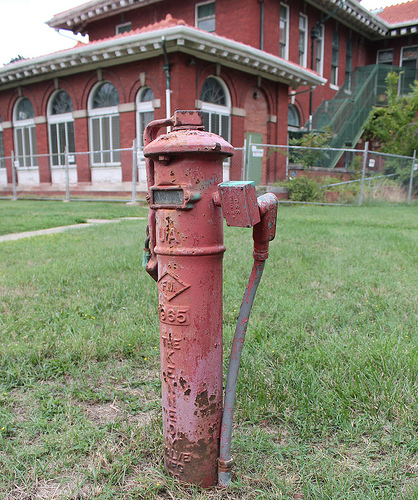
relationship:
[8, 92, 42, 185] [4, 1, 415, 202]
window on building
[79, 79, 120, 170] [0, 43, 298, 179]
window on building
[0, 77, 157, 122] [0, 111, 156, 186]
arched windows over narrow windows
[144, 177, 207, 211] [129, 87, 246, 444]
panel on hydrant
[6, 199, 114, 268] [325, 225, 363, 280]
walkway through grass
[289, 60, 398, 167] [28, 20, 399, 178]
stairwaay of building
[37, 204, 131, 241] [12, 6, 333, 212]
concrete pathway to building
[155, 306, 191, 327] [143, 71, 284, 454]
lettering on pipe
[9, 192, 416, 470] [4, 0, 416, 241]
field in front of house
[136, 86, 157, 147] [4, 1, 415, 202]
window on a building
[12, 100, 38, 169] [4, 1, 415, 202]
window on a building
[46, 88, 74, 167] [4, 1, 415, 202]
window on a building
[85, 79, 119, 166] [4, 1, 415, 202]
window on a building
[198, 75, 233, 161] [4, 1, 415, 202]
window on a building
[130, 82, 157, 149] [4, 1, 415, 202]
window on a building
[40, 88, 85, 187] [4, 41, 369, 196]
window on a building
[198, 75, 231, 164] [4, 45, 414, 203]
window on a building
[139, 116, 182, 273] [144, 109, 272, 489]
handle on side of hydrant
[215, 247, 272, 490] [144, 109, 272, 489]
pipe on side of hydrant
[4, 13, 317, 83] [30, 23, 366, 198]
roof on building